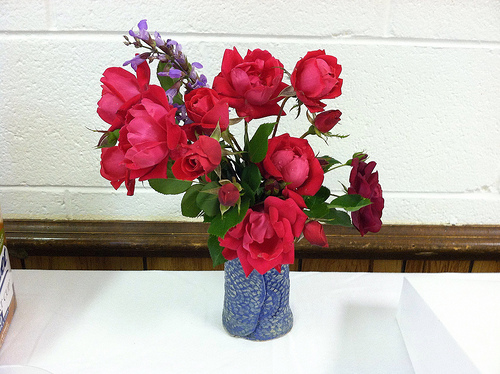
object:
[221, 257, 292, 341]
vase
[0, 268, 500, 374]
table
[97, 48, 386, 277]
roses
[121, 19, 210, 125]
flowers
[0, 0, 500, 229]
wall